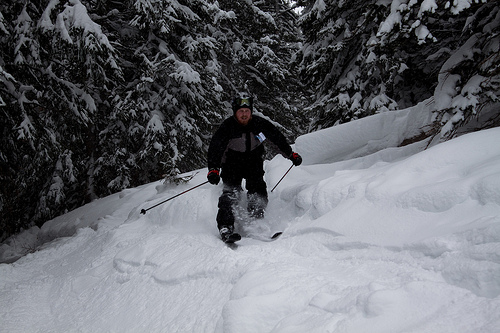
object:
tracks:
[308, 278, 394, 318]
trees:
[123, 0, 221, 182]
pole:
[131, 153, 307, 220]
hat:
[229, 94, 254, 111]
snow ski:
[259, 215, 305, 263]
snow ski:
[221, 229, 241, 245]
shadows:
[235, 212, 293, 258]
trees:
[333, 1, 414, 117]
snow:
[3, 99, 498, 331]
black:
[230, 154, 254, 174]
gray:
[232, 140, 244, 152]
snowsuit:
[195, 119, 294, 226]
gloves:
[206, 168, 223, 187]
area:
[1, 99, 499, 331]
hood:
[232, 94, 254, 109]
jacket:
[208, 115, 291, 167]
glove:
[291, 152, 305, 169]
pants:
[212, 153, 287, 242]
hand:
[289, 149, 304, 167]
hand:
[208, 170, 221, 184]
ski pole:
[138, 161, 304, 215]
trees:
[0, 3, 78, 240]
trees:
[423, 1, 498, 140]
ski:
[219, 228, 242, 245]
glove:
[207, 167, 221, 184]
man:
[197, 89, 311, 251]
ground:
[0, 163, 499, 331]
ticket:
[253, 129, 273, 145]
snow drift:
[330, 166, 449, 220]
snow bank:
[205, 82, 245, 216]